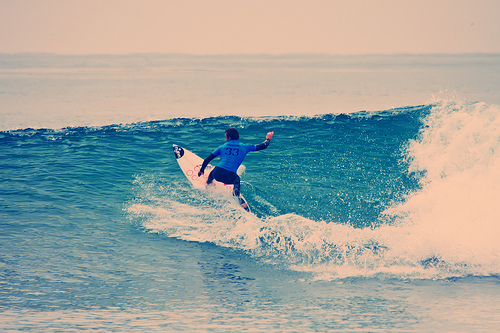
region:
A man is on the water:
[131, 101, 276, 271]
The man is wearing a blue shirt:
[195, 134, 306, 184]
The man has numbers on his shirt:
[212, 138, 313, 182]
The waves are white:
[297, 210, 498, 298]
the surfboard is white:
[155, 139, 315, 209]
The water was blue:
[41, 152, 223, 289]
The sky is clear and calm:
[51, 35, 258, 125]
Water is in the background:
[35, 28, 301, 138]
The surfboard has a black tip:
[159, 149, 198, 162]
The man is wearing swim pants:
[206, 149, 273, 214]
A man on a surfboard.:
[166, 115, 286, 232]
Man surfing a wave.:
[126, 110, 321, 265]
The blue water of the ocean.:
[1, 94, 496, 331]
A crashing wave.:
[360, 93, 495, 290]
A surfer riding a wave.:
[2, 84, 496, 324]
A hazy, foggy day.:
[2, 4, 491, 119]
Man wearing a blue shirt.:
[192, 119, 282, 219]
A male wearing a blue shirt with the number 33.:
[178, 112, 286, 220]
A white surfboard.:
[162, 137, 260, 219]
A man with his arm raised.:
[194, 119, 282, 216]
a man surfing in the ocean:
[150, 114, 299, 254]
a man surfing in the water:
[150, 99, 309, 263]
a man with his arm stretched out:
[220, 121, 282, 161]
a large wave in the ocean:
[288, 96, 483, 316]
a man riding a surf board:
[156, 116, 272, 216]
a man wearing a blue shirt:
[217, 124, 254, 172]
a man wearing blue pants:
[209, 162, 244, 202]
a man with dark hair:
[218, 116, 258, 151]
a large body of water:
[48, 48, 423, 117]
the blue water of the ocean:
[298, 100, 442, 257]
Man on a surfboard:
[171, 127, 274, 218]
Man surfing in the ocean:
[170, 125, 275, 215]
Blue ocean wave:
[0, 91, 498, 291]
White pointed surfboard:
[170, 140, 250, 217]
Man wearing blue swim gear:
[196, 127, 275, 204]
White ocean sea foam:
[126, 99, 498, 284]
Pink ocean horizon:
[0, 0, 498, 61]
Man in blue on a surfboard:
[170, 126, 276, 214]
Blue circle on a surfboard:
[171, 143, 185, 160]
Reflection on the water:
[197, 236, 255, 310]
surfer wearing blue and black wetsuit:
[196, 128, 271, 204]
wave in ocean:
[0, 97, 495, 330]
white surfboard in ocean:
[171, 142, 249, 214]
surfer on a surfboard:
[170, 124, 275, 217]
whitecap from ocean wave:
[374, 90, 499, 279]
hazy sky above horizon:
[0, 0, 497, 57]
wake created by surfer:
[120, 173, 373, 278]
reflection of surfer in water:
[195, 237, 261, 309]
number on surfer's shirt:
[222, 141, 244, 158]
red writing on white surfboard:
[185, 165, 221, 190]